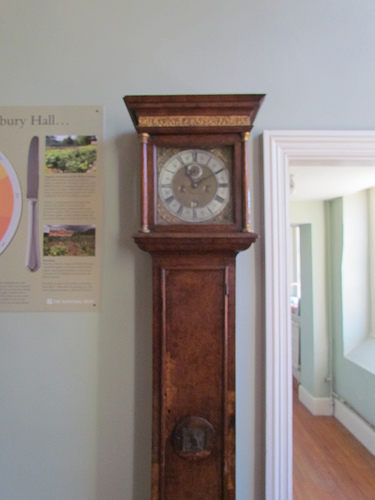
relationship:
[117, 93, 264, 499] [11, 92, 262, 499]
grandfather clock against wall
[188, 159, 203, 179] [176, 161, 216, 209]
square within circle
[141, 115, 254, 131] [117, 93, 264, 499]
trim on clock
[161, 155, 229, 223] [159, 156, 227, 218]
numerals in ring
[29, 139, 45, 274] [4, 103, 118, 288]
knife on poster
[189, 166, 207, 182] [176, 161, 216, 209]
circle at top of circle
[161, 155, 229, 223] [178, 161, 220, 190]
numerals at 11:10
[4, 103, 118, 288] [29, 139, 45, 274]
poster has knife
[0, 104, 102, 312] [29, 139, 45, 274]
poster has knife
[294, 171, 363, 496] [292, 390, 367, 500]
hall has floor boards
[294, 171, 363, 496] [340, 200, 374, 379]
hall has window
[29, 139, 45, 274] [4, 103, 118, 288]
butter knife on poster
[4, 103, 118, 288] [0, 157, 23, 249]
poster has bowl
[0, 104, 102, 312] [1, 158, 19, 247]
poster has bowl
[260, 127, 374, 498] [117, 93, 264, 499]
door frame next to clock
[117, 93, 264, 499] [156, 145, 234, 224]
clock has clockface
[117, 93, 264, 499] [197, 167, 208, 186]
clock has hour hand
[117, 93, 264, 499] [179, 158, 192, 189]
clock has minute hand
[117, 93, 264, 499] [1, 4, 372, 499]
clock in scene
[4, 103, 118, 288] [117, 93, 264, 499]
poster beside clock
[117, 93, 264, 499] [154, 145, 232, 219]
clock has circular face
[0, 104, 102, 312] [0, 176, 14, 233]
poster has peach color